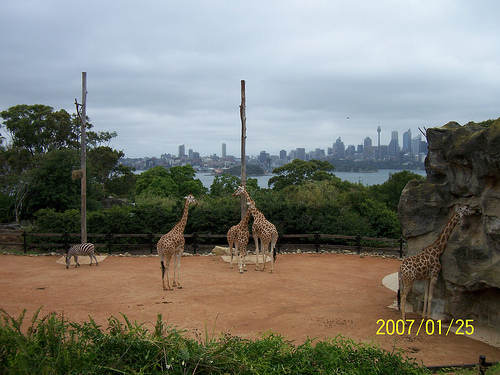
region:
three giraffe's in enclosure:
[145, 187, 286, 299]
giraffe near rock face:
[387, 200, 480, 321]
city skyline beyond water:
[345, 125, 405, 185]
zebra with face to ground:
[59, 242, 105, 278]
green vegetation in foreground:
[41, 314, 252, 367]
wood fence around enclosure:
[310, 228, 363, 259]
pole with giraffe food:
[61, 65, 91, 192]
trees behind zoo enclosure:
[45, 149, 157, 214]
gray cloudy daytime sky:
[296, 63, 388, 120]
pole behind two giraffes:
[227, 137, 249, 218]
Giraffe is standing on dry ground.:
[145, 187, 197, 311]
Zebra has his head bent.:
[47, 241, 107, 275]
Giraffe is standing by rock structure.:
[383, 198, 475, 338]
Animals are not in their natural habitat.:
[5, 2, 498, 372]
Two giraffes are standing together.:
[215, 182, 286, 284]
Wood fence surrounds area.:
[0, 222, 402, 266]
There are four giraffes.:
[140, 180, 475, 332]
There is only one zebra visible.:
[43, 235, 113, 286]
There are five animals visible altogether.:
[41, 180, 479, 332]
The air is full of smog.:
[3, 28, 499, 184]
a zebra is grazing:
[58, 240, 103, 272]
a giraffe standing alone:
[155, 192, 199, 291]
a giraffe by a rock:
[396, 201, 478, 326]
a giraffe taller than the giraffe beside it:
[223, 183, 283, 273]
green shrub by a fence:
[0, 299, 416, 374]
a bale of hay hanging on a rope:
[70, 162, 85, 182]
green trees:
[3, 101, 118, 228]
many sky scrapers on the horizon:
[123, 127, 425, 167]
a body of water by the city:
[113, 165, 423, 186]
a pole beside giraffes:
[238, 77, 253, 257]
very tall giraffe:
[158, 192, 199, 293]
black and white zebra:
[63, 241, 101, 271]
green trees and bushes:
[1, 103, 426, 255]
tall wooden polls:
[76, 72, 91, 258]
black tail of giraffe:
[157, 259, 169, 278]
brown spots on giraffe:
[405, 255, 432, 274]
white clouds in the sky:
[268, 47, 388, 97]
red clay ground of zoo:
[212, 290, 325, 321]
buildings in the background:
[110, 127, 427, 167]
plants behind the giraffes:
[1, 305, 421, 374]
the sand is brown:
[205, 262, 286, 314]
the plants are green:
[32, 290, 127, 362]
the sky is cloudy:
[147, 22, 341, 136]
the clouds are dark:
[114, 36, 300, 134]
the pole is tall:
[52, 58, 118, 263]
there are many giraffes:
[150, 165, 290, 294]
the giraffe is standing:
[110, 157, 220, 308]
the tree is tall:
[7, 82, 72, 254]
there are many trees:
[34, 91, 175, 233]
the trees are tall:
[97, 101, 299, 238]